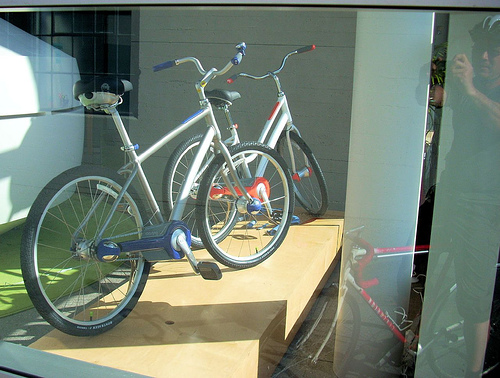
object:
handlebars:
[227, 44, 323, 81]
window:
[7, 9, 493, 375]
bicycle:
[158, 45, 338, 226]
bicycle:
[285, 217, 496, 376]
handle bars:
[151, 40, 246, 75]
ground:
[0, 199, 353, 373]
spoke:
[50, 209, 133, 304]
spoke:
[286, 140, 319, 200]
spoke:
[175, 156, 229, 223]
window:
[26, 9, 146, 122]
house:
[4, 6, 350, 213]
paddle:
[200, 263, 221, 282]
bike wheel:
[18, 164, 150, 338]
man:
[424, 16, 499, 359]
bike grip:
[296, 40, 316, 55]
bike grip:
[226, 70, 245, 82]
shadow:
[233, 233, 256, 239]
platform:
[33, 206, 365, 376]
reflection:
[337, 229, 469, 377]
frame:
[104, 81, 231, 249]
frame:
[209, 43, 311, 180]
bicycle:
[17, 37, 290, 339]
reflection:
[263, 7, 498, 377]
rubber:
[197, 142, 292, 270]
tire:
[206, 147, 291, 266]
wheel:
[4, 153, 159, 374]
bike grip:
[343, 235, 386, 288]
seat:
[73, 80, 136, 115]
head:
[473, 13, 500, 84]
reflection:
[463, 13, 498, 40]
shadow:
[66, 299, 283, 345]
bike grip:
[150, 54, 180, 70]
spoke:
[217, 164, 278, 256]